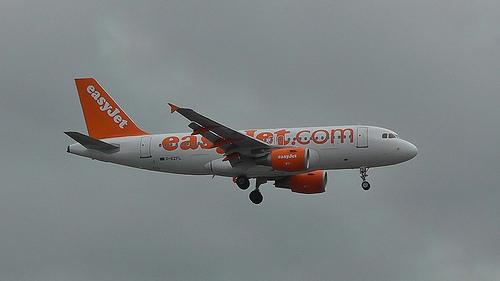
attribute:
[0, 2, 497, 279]
sky — gray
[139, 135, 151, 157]
door — for exiting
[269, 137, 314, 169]
turbine — orange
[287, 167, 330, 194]
turbine — orange